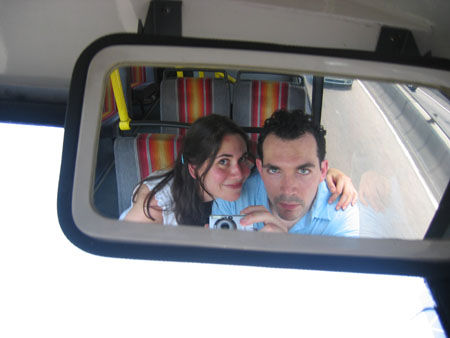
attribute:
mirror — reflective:
[91, 63, 449, 242]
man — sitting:
[206, 109, 361, 237]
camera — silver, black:
[208, 214, 254, 231]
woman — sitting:
[119, 115, 358, 228]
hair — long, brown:
[132, 113, 257, 226]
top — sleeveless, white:
[118, 167, 181, 227]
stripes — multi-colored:
[177, 75, 213, 134]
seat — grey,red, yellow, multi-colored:
[160, 67, 230, 134]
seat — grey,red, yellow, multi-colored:
[232, 69, 308, 154]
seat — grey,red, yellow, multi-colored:
[112, 119, 192, 218]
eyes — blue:
[267, 167, 311, 176]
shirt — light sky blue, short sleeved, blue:
[212, 167, 359, 238]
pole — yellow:
[110, 68, 131, 131]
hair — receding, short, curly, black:
[257, 109, 327, 171]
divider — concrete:
[360, 78, 450, 201]